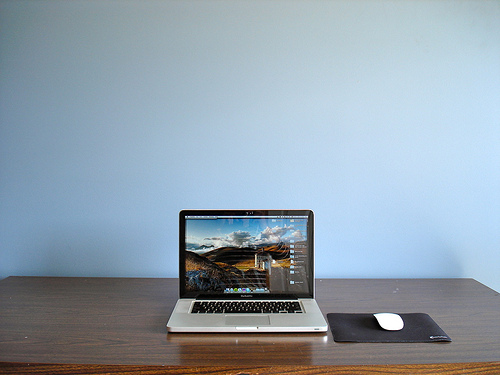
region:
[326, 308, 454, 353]
a black mouse pad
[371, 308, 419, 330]
white computer mouse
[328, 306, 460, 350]
mouse and mouse pad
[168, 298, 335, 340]
gray keyboard with black keys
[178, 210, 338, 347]
a laptop computer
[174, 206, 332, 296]
a computer screen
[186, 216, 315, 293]
picture of mountains and clouds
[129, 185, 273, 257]
a blue painted wall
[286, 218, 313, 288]
computer icons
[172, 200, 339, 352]
a turned on computer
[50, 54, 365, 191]
the wall is clear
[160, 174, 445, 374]
the laptop on desk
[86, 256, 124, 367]
the desk is made of wood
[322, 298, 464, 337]
mouse pad is black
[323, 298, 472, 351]
mousepad on the table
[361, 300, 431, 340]
mouse is white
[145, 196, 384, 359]
the laptop is open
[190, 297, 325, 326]
the keyboard is black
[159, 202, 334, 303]
the monitor has frame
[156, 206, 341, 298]
the frame is black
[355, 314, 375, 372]
the mousepad is black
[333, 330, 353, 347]
the mousepad is black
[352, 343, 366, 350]
the mousepad is black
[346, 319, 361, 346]
the mousepad is black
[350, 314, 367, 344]
the mousepad is black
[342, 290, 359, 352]
the mousepad is black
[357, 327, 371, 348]
the mousepad is black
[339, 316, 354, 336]
the mousepad is black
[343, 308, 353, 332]
the mousepad is black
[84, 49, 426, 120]
The wall is blue.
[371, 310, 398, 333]
The mouse is white.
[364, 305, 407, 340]
The mouse is on the table.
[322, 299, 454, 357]
The mouse pad is black.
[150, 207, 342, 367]
The computer is on.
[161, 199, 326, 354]
This is a laptop.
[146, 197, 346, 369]
The computer is on the table.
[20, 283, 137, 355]
The table is wood.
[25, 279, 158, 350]
The table is brown.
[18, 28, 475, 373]
This is an office.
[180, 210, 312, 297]
display area of laptop computer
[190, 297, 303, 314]
keyboard of a laptop computer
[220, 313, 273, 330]
touchpad on a laptop computer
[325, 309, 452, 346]
mousepad sitting on a table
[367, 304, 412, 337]
computer mouse sitting on a mousepad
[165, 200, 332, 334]
laptop sitting on a tabletop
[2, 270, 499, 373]
imitation wood tabletop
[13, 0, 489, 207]
blue wall in the background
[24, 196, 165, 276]
shadow on the wall cast by laptop computer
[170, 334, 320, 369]
reflection of laptop display reflecting off the table